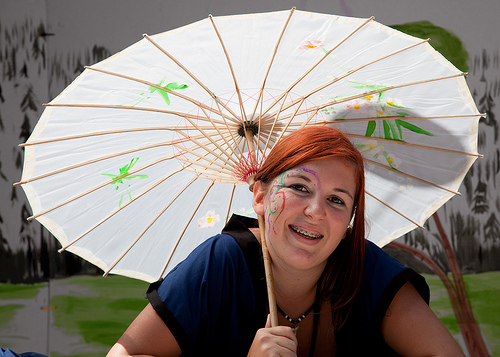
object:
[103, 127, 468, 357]
girl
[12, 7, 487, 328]
umbrella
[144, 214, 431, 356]
shirt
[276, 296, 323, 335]
necklace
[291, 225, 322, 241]
braces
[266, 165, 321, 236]
paint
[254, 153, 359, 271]
face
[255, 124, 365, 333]
hair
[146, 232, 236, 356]
sleeve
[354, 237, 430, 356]
sleeve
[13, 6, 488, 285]
frame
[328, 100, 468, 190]
shadow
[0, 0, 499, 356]
wall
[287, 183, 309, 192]
eye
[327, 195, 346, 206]
eye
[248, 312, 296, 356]
hand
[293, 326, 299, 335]
charm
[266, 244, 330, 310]
neck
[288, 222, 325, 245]
mouth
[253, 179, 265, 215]
ear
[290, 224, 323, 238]
upper teeth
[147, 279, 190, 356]
border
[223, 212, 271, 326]
border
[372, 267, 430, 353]
border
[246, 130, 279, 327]
stick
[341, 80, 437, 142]
flowers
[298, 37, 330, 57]
flowers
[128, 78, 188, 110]
flowers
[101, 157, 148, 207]
flowers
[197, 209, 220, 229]
flowers